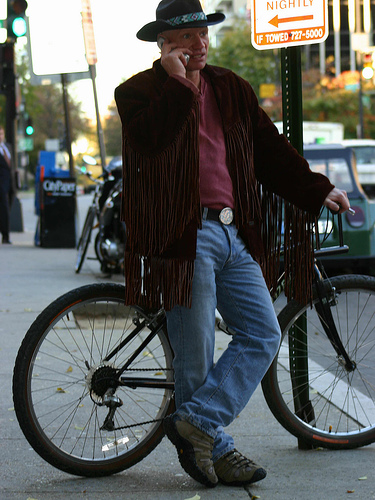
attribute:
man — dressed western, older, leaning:
[114, 1, 350, 488]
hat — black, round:
[137, 0, 225, 41]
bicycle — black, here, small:
[12, 202, 374, 477]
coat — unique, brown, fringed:
[114, 63, 333, 311]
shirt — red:
[177, 77, 235, 212]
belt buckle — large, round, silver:
[219, 207, 234, 224]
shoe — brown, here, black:
[165, 415, 218, 485]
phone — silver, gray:
[156, 38, 190, 63]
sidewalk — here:
[0, 189, 375, 499]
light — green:
[26, 125, 34, 133]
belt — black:
[199, 207, 238, 224]